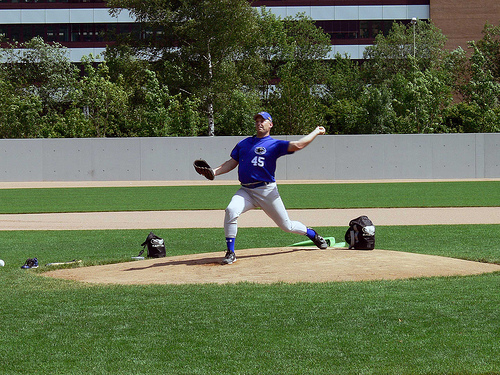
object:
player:
[194, 111, 327, 264]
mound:
[38, 245, 500, 285]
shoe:
[222, 252, 236, 264]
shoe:
[310, 228, 328, 250]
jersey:
[230, 135, 296, 184]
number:
[251, 156, 266, 167]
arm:
[286, 126, 326, 154]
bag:
[344, 215, 377, 251]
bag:
[137, 232, 167, 258]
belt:
[240, 181, 275, 189]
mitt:
[192, 159, 214, 180]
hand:
[192, 158, 214, 181]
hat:
[252, 112, 272, 123]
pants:
[224, 181, 308, 239]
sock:
[226, 237, 236, 253]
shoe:
[20, 256, 39, 269]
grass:
[0, 222, 500, 373]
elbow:
[295, 140, 304, 150]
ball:
[317, 125, 326, 132]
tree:
[269, 11, 329, 138]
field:
[0, 181, 500, 375]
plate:
[289, 236, 346, 248]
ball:
[0, 259, 6, 268]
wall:
[269, 133, 500, 183]